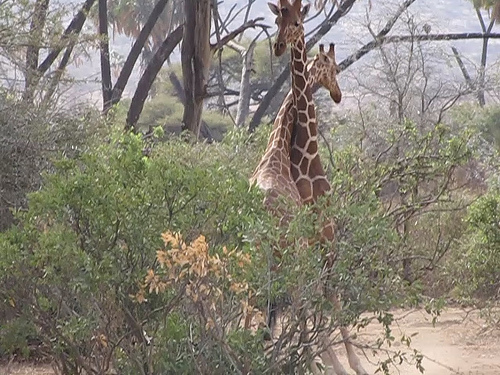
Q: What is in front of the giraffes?
A: A bush.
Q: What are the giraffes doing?
A: Hugging.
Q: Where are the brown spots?
A: On the giraffes.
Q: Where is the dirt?
A: On the ground.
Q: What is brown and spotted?
A: A giraffe's back.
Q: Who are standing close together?
A: Two giraffes.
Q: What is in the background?
A: Trees.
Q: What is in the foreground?
A: Bushes.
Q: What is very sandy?
A: Ground.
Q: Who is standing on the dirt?
A: Two giraffes.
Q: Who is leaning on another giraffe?
A: A giraffe.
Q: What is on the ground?
A: Dirt.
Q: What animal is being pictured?
A: Giraffe.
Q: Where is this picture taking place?
A: A forest.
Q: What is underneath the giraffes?
A: Dirt.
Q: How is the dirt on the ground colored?
A: Brown.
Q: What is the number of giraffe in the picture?
A: Two.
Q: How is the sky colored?
A: Blue.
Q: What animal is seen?
A: Giraffe.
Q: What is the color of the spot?
A: Brown.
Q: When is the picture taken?
A: Daytime.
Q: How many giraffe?
A: 2.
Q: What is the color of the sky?
A: Blue.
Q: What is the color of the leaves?
A: Green.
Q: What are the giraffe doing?
A: Standing.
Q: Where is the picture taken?
A: In the sAfari.